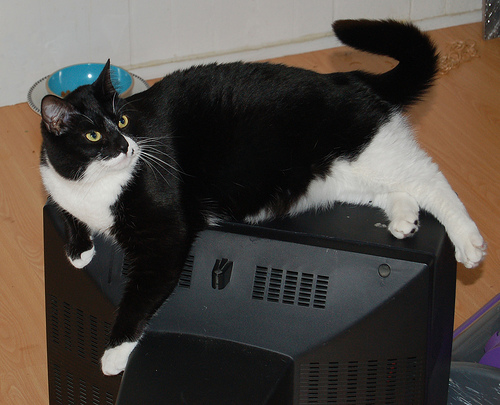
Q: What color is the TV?
A: Black.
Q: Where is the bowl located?
A: On hardwood floor.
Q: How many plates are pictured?
A: One.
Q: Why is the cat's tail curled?
A: It is calm.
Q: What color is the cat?
A: Black and white.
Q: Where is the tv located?
A: On the floor.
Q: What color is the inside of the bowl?
A: Blue.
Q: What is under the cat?
A: Tv.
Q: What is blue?
A: Dish.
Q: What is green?
A: Cat's eyes.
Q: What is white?
A: Whiskers.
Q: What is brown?
A: Table.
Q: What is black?
A: Cat.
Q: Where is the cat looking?
A: To the right.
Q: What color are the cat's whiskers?
A: White.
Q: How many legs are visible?
A: Four.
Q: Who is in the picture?
A: Cat.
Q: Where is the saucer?
A: Near the wall.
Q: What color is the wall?
A: White.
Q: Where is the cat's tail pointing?
A: To the left.